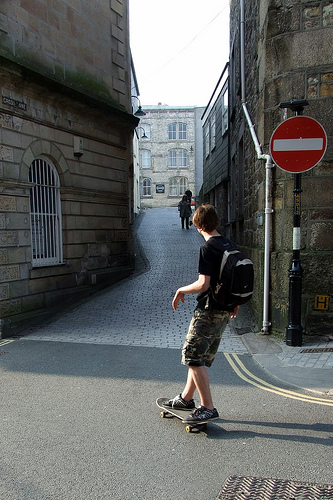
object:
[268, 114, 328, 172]
sign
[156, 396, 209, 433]
board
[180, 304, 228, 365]
cargo pants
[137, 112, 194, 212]
building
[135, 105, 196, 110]
roof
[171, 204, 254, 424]
boy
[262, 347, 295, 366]
stone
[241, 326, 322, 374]
sidewalk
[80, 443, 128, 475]
black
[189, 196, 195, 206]
red car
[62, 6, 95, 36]
surface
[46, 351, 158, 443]
green leaf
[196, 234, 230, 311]
dark shirt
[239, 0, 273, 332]
drain pipe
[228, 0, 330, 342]
drain wall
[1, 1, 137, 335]
drain wall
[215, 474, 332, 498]
grate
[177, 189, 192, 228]
woman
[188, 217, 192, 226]
bag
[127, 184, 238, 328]
walkway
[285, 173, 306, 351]
post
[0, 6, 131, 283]
wall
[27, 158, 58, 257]
bars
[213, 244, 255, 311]
back pack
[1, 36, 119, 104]
mold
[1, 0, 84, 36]
wall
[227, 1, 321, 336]
wall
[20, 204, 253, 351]
walk way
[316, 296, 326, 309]
letter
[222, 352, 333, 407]
double lines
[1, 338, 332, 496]
road